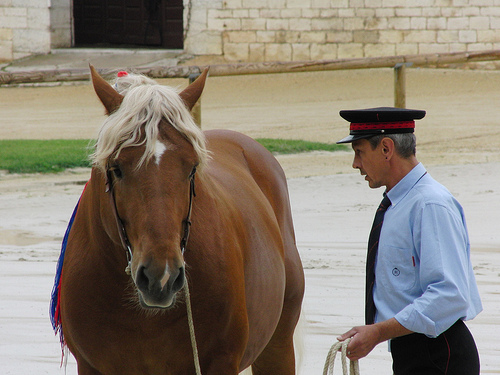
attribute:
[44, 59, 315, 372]
horse — brown, large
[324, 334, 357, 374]
rope — white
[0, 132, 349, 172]
grass — green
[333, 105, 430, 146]
cap — black, red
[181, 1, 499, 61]
wall — dirty, white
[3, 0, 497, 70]
wall — white, brick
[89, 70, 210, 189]
hair — white, blonde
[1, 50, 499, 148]
fence — wooden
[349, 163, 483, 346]
shirt — blue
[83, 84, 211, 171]
forelock — blond